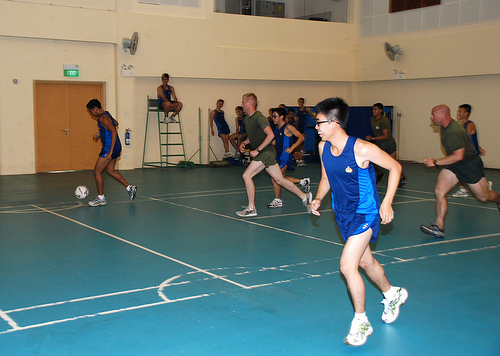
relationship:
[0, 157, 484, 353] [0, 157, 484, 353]
pattern on floor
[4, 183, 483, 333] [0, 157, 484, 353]
lines on floor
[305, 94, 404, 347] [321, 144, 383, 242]
man wears uniform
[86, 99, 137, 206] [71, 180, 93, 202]
player kicks ball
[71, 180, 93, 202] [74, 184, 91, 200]
ball for ball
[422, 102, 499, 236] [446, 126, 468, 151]
man runs in green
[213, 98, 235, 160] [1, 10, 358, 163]
person leans on wall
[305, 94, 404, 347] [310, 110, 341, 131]
man wears glasses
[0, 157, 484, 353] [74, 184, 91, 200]
floor for ball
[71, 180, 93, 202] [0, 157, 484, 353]
ball on floor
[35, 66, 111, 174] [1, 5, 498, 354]
doors entering gym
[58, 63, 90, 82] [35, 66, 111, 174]
exit sign above doors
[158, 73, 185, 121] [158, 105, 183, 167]
person on ladder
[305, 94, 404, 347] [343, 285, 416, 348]
man wears sneakers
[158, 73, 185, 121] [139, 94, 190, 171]
person sits on chair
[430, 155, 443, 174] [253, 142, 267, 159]
watch on wrist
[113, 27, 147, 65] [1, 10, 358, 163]
fan on wall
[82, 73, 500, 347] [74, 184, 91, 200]
group plays ball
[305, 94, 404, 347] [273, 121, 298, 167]
man in blue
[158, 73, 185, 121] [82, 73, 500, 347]
person watching group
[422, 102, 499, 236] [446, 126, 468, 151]
man in green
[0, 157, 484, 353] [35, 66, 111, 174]
floor to doors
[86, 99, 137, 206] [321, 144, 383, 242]
athlete in uniform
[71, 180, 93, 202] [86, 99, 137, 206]
ball kicked by man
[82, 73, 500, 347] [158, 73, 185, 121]
game watched by person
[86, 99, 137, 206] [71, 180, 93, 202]
player dribbles ball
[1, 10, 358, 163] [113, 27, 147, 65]
wall mounted fan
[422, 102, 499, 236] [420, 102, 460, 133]
man shaved head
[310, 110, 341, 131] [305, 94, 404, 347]
glasses on man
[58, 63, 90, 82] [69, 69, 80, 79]
exit sign letters are green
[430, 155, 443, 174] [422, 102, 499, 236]
watch on man